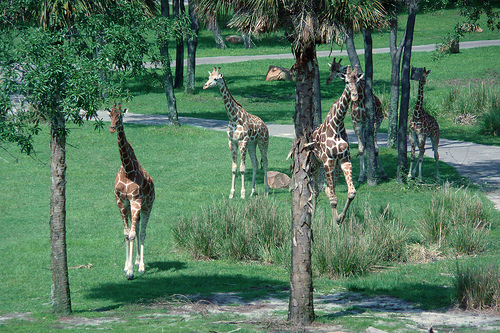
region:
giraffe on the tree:
[319, 71, 360, 236]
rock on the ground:
[266, 159, 283, 203]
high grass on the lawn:
[321, 215, 423, 265]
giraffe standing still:
[171, 70, 274, 214]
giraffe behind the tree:
[326, 55, 383, 138]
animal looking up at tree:
[407, 53, 424, 169]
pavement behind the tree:
[134, 113, 229, 133]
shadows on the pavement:
[440, 160, 498, 190]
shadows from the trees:
[106, 268, 261, 309]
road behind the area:
[188, 53, 287, 61]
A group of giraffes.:
[53, 50, 474, 279]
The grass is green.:
[133, 129, 229, 198]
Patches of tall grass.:
[178, 188, 499, 268]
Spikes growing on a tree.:
[282, 130, 324, 245]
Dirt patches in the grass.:
[205, 285, 496, 330]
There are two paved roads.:
[0, 32, 499, 184]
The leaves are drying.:
[200, 0, 387, 50]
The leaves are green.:
[5, 5, 160, 115]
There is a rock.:
[260, 155, 295, 205]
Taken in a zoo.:
[0, 0, 498, 326]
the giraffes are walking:
[95, 30, 471, 247]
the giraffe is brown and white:
[263, 42, 380, 237]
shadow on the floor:
[279, 264, 431, 323]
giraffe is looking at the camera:
[317, 42, 388, 119]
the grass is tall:
[321, 190, 485, 272]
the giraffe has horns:
[330, 55, 376, 94]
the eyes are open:
[340, 72, 360, 89]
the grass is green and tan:
[336, 201, 443, 278]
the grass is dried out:
[402, 226, 452, 273]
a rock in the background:
[243, 30, 305, 102]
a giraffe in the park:
[106, 98, 159, 276]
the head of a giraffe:
[203, 63, 225, 94]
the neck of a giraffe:
[217, 86, 240, 113]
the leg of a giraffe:
[343, 160, 354, 221]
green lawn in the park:
[136, 122, 205, 192]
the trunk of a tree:
[286, 163, 318, 325]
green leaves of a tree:
[12, 33, 124, 122]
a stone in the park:
[266, 59, 292, 84]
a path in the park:
[197, 55, 294, 66]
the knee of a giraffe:
[346, 184, 362, 203]